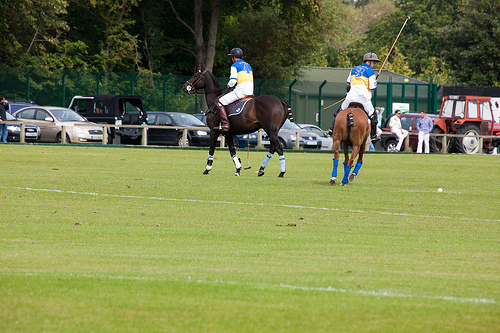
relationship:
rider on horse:
[220, 40, 254, 116] [188, 69, 294, 185]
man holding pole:
[338, 51, 374, 112] [383, 20, 408, 52]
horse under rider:
[188, 69, 294, 185] [220, 40, 254, 116]